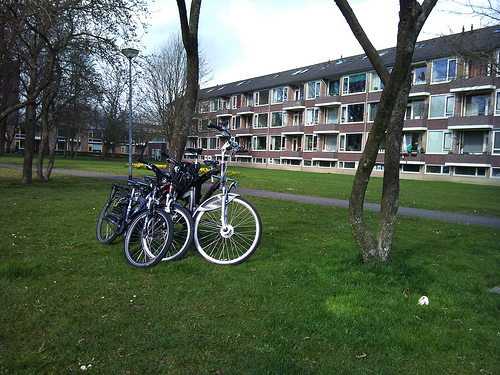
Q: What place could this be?
A: It is a lawn.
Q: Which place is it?
A: It is a lawn.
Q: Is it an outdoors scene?
A: Yes, it is outdoors.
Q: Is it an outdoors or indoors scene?
A: It is outdoors.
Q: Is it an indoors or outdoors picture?
A: It is outdoors.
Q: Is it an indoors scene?
A: No, it is outdoors.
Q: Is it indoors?
A: No, it is outdoors.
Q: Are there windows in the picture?
A: Yes, there is a window.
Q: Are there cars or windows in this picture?
A: Yes, there is a window.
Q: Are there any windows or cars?
A: Yes, there is a window.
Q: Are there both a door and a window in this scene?
A: No, there is a window but no doors.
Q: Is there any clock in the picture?
A: No, there are no clocks.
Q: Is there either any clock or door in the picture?
A: No, there are no clocks or doors.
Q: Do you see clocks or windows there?
A: Yes, there is a window.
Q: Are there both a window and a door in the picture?
A: No, there is a window but no doors.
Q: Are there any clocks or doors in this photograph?
A: No, there are no doors or clocks.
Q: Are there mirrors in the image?
A: No, there are no mirrors.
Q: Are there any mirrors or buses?
A: No, there are no mirrors or buses.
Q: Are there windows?
A: Yes, there is a window.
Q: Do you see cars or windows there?
A: Yes, there is a window.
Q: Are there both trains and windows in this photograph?
A: No, there is a window but no trains.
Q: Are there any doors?
A: No, there are no doors.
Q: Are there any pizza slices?
A: No, there are no pizza slices.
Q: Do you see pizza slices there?
A: No, there are no pizza slices.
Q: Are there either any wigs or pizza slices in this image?
A: No, there are no pizza slices or wigs.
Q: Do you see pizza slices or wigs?
A: No, there are no pizza slices or wigs.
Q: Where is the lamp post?
A: The lamp post is on the grass.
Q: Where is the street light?
A: The lamp post is on the grass.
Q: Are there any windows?
A: Yes, there is a window.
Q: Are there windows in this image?
A: Yes, there is a window.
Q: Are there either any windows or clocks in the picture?
A: Yes, there is a window.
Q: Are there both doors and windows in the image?
A: No, there is a window but no doors.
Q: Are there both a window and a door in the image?
A: No, there is a window but no doors.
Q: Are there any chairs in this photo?
A: No, there are no chairs.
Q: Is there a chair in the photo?
A: No, there are no chairs.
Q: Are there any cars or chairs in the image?
A: No, there are no chairs or cars.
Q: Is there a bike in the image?
A: Yes, there are bikes.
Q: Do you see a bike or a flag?
A: Yes, there are bikes.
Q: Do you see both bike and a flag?
A: No, there are bikes but no flags.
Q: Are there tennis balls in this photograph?
A: No, there are no tennis balls.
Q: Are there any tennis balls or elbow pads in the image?
A: No, there are no tennis balls or elbow pads.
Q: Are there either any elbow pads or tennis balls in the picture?
A: No, there are no tennis balls or elbow pads.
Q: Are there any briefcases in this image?
A: No, there are no briefcases.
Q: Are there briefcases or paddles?
A: No, there are no briefcases or paddles.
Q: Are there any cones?
A: No, there are no cones.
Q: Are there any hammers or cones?
A: No, there are no cones or hammers.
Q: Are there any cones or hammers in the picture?
A: No, there are no cones or hammers.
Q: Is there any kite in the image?
A: No, there are no kites.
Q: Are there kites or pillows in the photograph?
A: No, there are no kites or pillows.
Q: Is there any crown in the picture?
A: No, there are no crowns.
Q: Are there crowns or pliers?
A: No, there are no crowns or pliers.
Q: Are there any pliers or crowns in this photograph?
A: No, there are no crowns or pliers.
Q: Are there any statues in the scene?
A: No, there are no statues.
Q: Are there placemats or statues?
A: No, there are no statues or placemats.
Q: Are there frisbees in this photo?
A: No, there are no frisbees.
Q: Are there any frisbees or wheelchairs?
A: No, there are no frisbees or wheelchairs.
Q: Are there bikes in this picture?
A: Yes, there is a bike.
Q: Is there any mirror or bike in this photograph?
A: Yes, there is a bike.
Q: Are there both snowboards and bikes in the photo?
A: No, there is a bike but no snowboards.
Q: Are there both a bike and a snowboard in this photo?
A: No, there is a bike but no snowboards.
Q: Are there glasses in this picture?
A: No, there are no glasses.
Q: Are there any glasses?
A: No, there are no glasses.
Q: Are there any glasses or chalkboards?
A: No, there are no glasses or chalkboards.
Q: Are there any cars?
A: No, there are no cars.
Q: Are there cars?
A: No, there are no cars.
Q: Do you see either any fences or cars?
A: No, there are no cars or fences.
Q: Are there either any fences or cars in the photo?
A: No, there are no cars or fences.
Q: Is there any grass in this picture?
A: Yes, there is grass.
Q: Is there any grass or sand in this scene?
A: Yes, there is grass.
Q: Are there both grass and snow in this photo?
A: No, there is grass but no snow.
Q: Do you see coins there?
A: No, there are no coins.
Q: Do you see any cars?
A: No, there are no cars.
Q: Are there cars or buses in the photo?
A: No, there are no cars or buses.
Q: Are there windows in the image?
A: Yes, there is a window.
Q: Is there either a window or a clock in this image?
A: Yes, there is a window.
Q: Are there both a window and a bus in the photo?
A: No, there is a window but no buses.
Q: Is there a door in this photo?
A: No, there are no doors.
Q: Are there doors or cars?
A: No, there are no doors or cars.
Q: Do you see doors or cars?
A: No, there are no doors or cars.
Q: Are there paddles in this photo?
A: No, there are no paddles.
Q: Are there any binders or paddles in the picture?
A: No, there are no paddles or binders.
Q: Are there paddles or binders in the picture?
A: No, there are no paddles or binders.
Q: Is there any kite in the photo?
A: No, there are no kites.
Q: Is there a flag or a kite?
A: No, there are no kites or flags.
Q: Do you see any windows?
A: Yes, there is a window.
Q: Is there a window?
A: Yes, there is a window.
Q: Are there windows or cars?
A: Yes, there is a window.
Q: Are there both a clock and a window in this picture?
A: No, there is a window but no clocks.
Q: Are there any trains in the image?
A: No, there are no trains.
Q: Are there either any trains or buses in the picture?
A: No, there are no trains or buses.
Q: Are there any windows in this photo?
A: Yes, there is a window.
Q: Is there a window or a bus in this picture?
A: Yes, there is a window.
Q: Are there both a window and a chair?
A: No, there is a window but no chairs.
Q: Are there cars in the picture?
A: No, there are no cars.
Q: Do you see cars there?
A: No, there are no cars.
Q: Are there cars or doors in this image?
A: No, there are no cars or doors.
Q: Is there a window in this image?
A: Yes, there is a window.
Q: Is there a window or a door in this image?
A: Yes, there is a window.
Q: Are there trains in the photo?
A: No, there are no trains.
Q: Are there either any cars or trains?
A: No, there are no trains or cars.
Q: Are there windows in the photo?
A: Yes, there is a window.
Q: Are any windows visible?
A: Yes, there is a window.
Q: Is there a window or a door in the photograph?
A: Yes, there is a window.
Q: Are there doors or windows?
A: Yes, there is a window.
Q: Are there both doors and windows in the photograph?
A: No, there is a window but no doors.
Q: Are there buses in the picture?
A: No, there are no buses.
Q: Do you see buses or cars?
A: No, there are no buses or cars.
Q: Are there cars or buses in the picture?
A: No, there are no buses or cars.